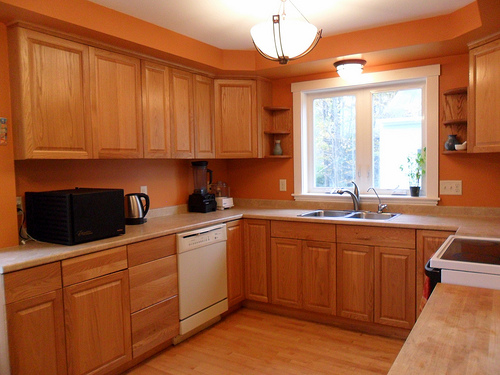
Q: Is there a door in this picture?
A: Yes, there are doors.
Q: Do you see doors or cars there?
A: Yes, there are doors.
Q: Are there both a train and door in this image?
A: No, there are doors but no trains.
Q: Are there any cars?
A: No, there are no cars.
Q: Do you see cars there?
A: No, there are no cars.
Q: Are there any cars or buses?
A: No, there are no cars or buses.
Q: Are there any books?
A: No, there are no books.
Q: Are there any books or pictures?
A: No, there are no books or pictures.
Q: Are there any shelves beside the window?
A: Yes, there is a shelf beside the window.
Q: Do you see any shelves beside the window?
A: Yes, there is a shelf beside the window.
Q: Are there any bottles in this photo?
A: No, there are no bottles.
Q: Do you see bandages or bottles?
A: No, there are no bottles or bandages.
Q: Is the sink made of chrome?
A: Yes, the sink is made of chrome.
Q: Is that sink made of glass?
A: No, the sink is made of chrome.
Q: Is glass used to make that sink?
A: No, the sink is made of chrome.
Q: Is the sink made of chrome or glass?
A: The sink is made of chrome.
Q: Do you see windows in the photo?
A: Yes, there is a window.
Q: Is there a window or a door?
A: Yes, there is a window.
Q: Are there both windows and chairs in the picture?
A: No, there is a window but no chairs.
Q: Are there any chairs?
A: No, there are no chairs.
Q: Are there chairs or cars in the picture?
A: No, there are no chairs or cars.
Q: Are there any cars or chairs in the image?
A: No, there are no chairs or cars.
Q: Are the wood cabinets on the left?
A: Yes, the cabinets are on the left of the image.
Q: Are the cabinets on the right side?
A: No, the cabinets are on the left of the image.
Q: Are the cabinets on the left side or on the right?
A: The cabinets are on the left of the image.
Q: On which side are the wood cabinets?
A: The cabinets are on the left of the image.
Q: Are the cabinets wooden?
A: Yes, the cabinets are wooden.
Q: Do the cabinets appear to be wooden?
A: Yes, the cabinets are wooden.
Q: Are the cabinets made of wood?
A: Yes, the cabinets are made of wood.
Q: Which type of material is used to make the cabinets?
A: The cabinets are made of wood.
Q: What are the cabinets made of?
A: The cabinets are made of wood.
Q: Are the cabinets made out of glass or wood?
A: The cabinets are made of wood.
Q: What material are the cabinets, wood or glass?
A: The cabinets are made of wood.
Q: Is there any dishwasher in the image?
A: Yes, there is a dishwasher.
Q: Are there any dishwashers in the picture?
A: Yes, there is a dishwasher.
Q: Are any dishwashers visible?
A: Yes, there is a dishwasher.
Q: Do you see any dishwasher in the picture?
A: Yes, there is a dishwasher.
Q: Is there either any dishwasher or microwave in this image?
A: Yes, there is a dishwasher.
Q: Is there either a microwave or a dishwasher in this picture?
A: Yes, there is a dishwasher.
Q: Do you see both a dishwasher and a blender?
A: Yes, there are both a dishwasher and a blender.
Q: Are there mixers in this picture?
A: No, there are no mixers.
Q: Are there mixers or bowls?
A: No, there are no mixers or bowls.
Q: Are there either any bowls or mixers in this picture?
A: No, there are no mixers or bowls.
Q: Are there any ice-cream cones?
A: No, there are no ice-cream cones.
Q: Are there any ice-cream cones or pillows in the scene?
A: No, there are no ice-cream cones or pillows.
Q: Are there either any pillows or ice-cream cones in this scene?
A: No, there are no ice-cream cones or pillows.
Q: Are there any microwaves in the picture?
A: Yes, there is a microwave.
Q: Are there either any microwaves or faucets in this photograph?
A: Yes, there is a microwave.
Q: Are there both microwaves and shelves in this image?
A: Yes, there are both a microwave and a shelf.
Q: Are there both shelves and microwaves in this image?
A: Yes, there are both a microwave and a shelf.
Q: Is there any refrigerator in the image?
A: No, there are no refrigerators.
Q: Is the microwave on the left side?
A: Yes, the microwave is on the left of the image.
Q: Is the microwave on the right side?
A: No, the microwave is on the left of the image.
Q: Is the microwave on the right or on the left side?
A: The microwave is on the left of the image.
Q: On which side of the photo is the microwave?
A: The microwave is on the left of the image.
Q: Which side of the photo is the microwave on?
A: The microwave is on the left of the image.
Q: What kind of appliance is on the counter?
A: The appliance is a microwave.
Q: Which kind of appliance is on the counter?
A: The appliance is a microwave.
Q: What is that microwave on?
A: The microwave is on the counter.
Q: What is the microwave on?
A: The microwave is on the counter.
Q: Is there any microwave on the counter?
A: Yes, there is a microwave on the counter.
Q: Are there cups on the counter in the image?
A: No, there is a microwave on the counter.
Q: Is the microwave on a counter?
A: Yes, the microwave is on a counter.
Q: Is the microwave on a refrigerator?
A: No, the microwave is on a counter.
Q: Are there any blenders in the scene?
A: Yes, there is a blender.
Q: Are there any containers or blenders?
A: Yes, there is a blender.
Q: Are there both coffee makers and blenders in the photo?
A: No, there is a blender but no coffee makers.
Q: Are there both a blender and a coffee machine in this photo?
A: No, there is a blender but no coffee makers.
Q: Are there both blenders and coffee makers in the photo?
A: No, there is a blender but no coffee makers.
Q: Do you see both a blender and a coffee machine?
A: No, there is a blender but no coffee makers.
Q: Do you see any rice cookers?
A: No, there are no rice cookers.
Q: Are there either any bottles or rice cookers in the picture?
A: No, there are no rice cookers or bottles.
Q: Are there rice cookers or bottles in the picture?
A: No, there are no rice cookers or bottles.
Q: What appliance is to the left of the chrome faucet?
A: The appliance is a blender.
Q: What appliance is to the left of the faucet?
A: The appliance is a blender.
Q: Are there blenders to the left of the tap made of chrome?
A: Yes, there is a blender to the left of the tap.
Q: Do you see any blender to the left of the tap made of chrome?
A: Yes, there is a blender to the left of the tap.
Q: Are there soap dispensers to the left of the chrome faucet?
A: No, there is a blender to the left of the faucet.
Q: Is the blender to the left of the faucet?
A: Yes, the blender is to the left of the faucet.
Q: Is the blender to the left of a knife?
A: No, the blender is to the left of the faucet.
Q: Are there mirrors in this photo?
A: No, there are no mirrors.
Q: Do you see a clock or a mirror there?
A: No, there are no mirrors or clocks.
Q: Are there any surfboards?
A: No, there are no surfboards.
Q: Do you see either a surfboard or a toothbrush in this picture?
A: No, there are no surfboards or toothbrushes.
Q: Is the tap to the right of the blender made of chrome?
A: Yes, the faucet is made of chrome.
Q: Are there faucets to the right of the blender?
A: Yes, there is a faucet to the right of the blender.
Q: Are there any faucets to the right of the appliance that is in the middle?
A: Yes, there is a faucet to the right of the blender.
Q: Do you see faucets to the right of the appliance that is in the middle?
A: Yes, there is a faucet to the right of the blender.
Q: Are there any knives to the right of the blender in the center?
A: No, there is a faucet to the right of the blender.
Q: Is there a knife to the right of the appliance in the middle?
A: No, there is a faucet to the right of the blender.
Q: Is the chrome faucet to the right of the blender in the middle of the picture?
A: Yes, the faucet is to the right of the blender.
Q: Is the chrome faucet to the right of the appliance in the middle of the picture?
A: Yes, the faucet is to the right of the blender.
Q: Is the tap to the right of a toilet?
A: No, the tap is to the right of the blender.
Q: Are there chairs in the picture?
A: No, there are no chairs.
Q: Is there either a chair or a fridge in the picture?
A: No, there are no chairs or refrigerators.